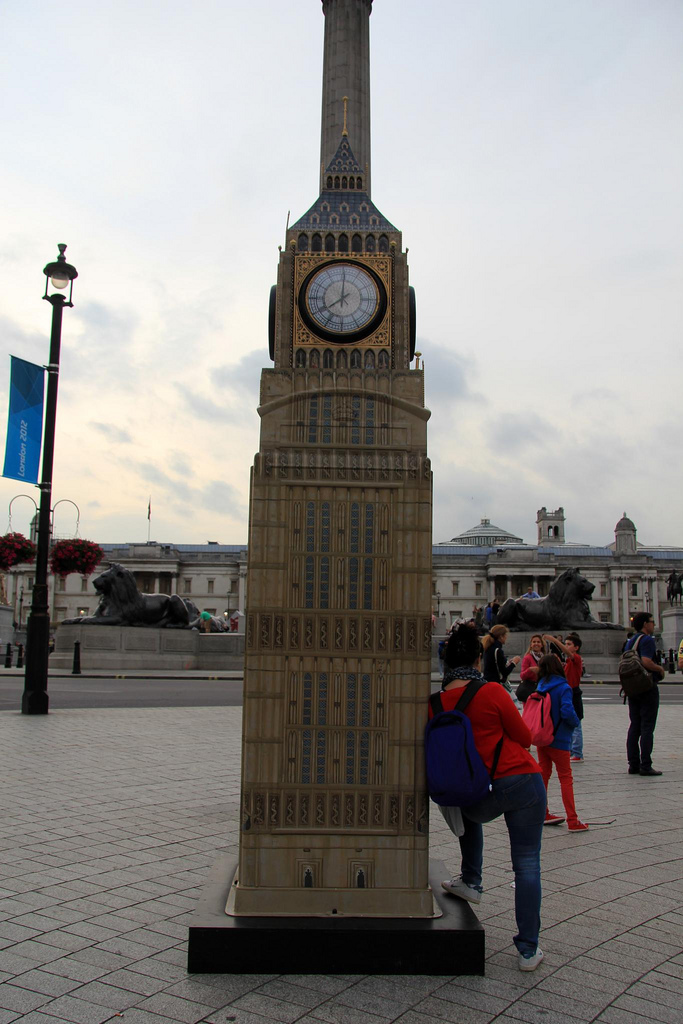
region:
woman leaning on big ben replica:
[184, 0, 546, 981]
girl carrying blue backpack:
[417, 618, 551, 970]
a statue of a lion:
[57, 561, 218, 632]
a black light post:
[4, 256, 78, 721]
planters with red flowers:
[0, 486, 106, 583]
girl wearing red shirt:
[424, 621, 554, 974]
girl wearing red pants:
[521, 654, 592, 836]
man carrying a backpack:
[613, 608, 674, 780]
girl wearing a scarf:
[424, 622, 550, 969]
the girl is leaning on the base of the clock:
[376, 586, 594, 988]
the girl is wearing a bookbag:
[399, 676, 510, 829]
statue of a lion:
[471, 546, 608, 636]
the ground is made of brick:
[532, 847, 649, 1005]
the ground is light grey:
[554, 842, 661, 1004]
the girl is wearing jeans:
[443, 734, 573, 951]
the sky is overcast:
[370, 328, 662, 527]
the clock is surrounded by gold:
[267, 221, 399, 350]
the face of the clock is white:
[261, 242, 400, 337]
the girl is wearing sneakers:
[428, 854, 551, 976]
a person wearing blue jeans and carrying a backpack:
[432, 606, 557, 978]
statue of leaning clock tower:
[211, 4, 459, 921]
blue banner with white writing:
[1, 353, 48, 486]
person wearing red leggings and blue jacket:
[514, 648, 592, 841]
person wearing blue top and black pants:
[611, 604, 682, 791]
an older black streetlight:
[31, 240, 84, 727]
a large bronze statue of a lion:
[54, 564, 211, 634]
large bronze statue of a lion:
[488, 562, 629, 643]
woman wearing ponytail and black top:
[476, 619, 526, 695]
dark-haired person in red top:
[562, 630, 589, 728]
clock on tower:
[226, 1, 449, 919]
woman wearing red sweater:
[423, 618, 551, 974]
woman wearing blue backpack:
[429, 619, 545, 973]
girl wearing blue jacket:
[518, 649, 593, 832]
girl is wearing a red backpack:
[518, 654, 593, 833]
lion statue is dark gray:
[487, 562, 624, 633]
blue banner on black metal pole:
[8, 240, 82, 713]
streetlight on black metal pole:
[20, 240, 77, 718]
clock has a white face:
[297, 256, 388, 345]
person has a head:
[438, 631, 483, 673]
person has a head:
[484, 625, 510, 645]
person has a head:
[529, 636, 542, 655]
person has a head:
[538, 654, 561, 677]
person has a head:
[564, 635, 581, 653]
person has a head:
[633, 610, 656, 630]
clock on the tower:
[301, 259, 388, 331]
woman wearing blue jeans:
[463, 755, 560, 926]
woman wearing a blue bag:
[421, 692, 495, 812]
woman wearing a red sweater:
[433, 675, 544, 780]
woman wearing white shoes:
[439, 867, 550, 980]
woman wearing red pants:
[532, 739, 592, 832]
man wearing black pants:
[617, 676, 666, 763]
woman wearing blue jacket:
[532, 676, 579, 737]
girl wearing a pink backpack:
[518, 683, 559, 749]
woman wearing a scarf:
[437, 657, 487, 688]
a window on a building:
[52, 568, 72, 597]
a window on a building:
[78, 574, 86, 589]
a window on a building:
[180, 574, 190, 596]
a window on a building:
[205, 577, 214, 595]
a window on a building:
[228, 574, 232, 589]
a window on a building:
[471, 581, 481, 599]